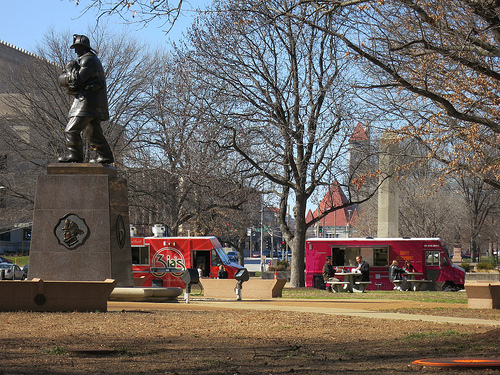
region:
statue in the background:
[30, 22, 148, 188]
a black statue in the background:
[14, 22, 199, 322]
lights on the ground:
[211, 257, 284, 325]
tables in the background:
[299, 249, 481, 328]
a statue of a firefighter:
[29, 31, 136, 278]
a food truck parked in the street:
[132, 235, 239, 287]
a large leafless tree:
[194, 1, 356, 271]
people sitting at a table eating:
[321, 256, 373, 296]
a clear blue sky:
[4, 3, 74, 25]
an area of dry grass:
[26, 309, 376, 339]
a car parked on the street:
[3, 260, 28, 279]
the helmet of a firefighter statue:
[69, 35, 99, 51]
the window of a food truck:
[133, 246, 148, 261]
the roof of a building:
[314, 182, 354, 234]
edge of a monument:
[94, 222, 114, 254]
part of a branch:
[263, 167, 295, 196]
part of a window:
[368, 245, 387, 270]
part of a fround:
[235, 316, 272, 341]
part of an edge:
[75, 286, 89, 293]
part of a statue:
[80, 120, 107, 160]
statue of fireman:
[39, 33, 134, 175]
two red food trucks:
[113, 231, 498, 321]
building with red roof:
[298, 118, 383, 286]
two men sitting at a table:
[313, 248, 371, 307]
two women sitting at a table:
[388, 253, 443, 293]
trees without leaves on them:
[16, 35, 405, 335]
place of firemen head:
[46, 206, 98, 263]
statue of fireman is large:
[26, 26, 149, 306]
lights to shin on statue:
[171, 263, 268, 314]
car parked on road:
[1, 253, 29, 287]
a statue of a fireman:
[35, 24, 136, 171]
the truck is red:
[294, 220, 471, 321]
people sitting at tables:
[313, 248, 442, 309]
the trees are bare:
[108, 3, 495, 244]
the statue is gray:
[44, 31, 129, 183]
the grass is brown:
[5, 298, 492, 372]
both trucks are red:
[122, 221, 477, 309]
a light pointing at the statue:
[215, 256, 269, 323]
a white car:
[0, 258, 24, 284]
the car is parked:
[1, 251, 25, 286]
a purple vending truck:
[301, 225, 478, 305]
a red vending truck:
[109, 223, 245, 297]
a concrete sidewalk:
[165, 293, 496, 333]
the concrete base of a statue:
[18, 161, 144, 294]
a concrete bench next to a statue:
[0, 264, 126, 317]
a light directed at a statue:
[232, 264, 258, 299]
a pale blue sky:
[1, 3, 494, 211]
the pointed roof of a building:
[311, 173, 365, 233]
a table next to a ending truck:
[328, 263, 381, 296]